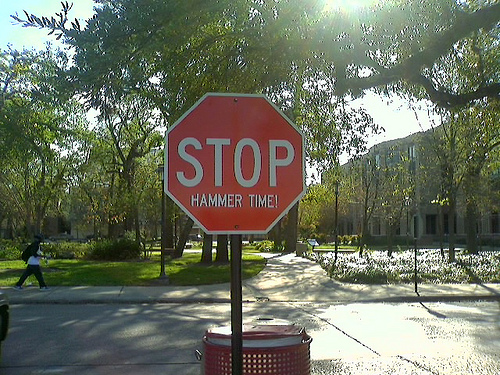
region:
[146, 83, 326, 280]
The stop sign is red.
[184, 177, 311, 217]
the sign has Hammer Time written under the word stop.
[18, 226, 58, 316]
A person walking on the sidewalk.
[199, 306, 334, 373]
the garbage can is red.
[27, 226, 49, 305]
The person has on a white shirt.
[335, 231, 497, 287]
Flowers are planted in the park.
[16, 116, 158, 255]
A lot of trees in the park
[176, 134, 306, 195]
The sign has white writing.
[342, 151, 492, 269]
A building sits in the background.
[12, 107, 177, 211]
The trees are green and tall.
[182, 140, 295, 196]
bold white words on red sign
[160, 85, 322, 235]
rectangular red sign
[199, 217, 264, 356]
black post on red sign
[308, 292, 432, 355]
bright sunshine on the road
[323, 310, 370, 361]
lines going across the road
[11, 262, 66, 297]
man wearing black pants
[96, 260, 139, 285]
well manicured green grass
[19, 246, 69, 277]
man wearing white shirt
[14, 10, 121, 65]
large branch on green tree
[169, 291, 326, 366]
red container with holes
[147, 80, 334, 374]
There is a stop sign.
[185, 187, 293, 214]
The words hammer time are on the sign.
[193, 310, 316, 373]
There is a red trash bin.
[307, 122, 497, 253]
There is a building in the background.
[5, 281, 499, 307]
There is a sidewalk.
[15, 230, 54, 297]
A person walks on the sidewalk.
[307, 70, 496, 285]
There are several trees.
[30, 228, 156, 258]
There are bushes and vegetation.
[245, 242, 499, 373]
Sunlight shines on the street and sidewalk.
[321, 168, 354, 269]
There is a lamp post.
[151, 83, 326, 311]
Red stop sign on sidewalk.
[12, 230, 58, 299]
Person walking down sidewalk.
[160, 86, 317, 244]
Red stop sign with white writing.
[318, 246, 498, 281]
White flowers growing next to sidewalk.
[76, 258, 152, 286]
Grass growing next to sidewalk.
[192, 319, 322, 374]
Trash container on sidewalk.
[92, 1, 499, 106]
Branch of tree growing next to sidewalk.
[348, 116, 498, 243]
Building next to sidewalk.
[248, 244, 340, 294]
Path leading from sidewalk.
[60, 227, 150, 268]
Shrubbery growing under trees.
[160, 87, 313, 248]
stop sign with funny saying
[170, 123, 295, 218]
funny saying "stop hammer time!" on stop sign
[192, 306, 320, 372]
red trash can on street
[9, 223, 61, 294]
man walking on curb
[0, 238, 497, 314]
sidewalk near park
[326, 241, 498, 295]
white flower garden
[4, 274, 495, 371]
thin roadway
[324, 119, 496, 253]
tall multistory buildings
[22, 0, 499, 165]
overhanging leafy green branches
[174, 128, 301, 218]
mc hammer catchphrase